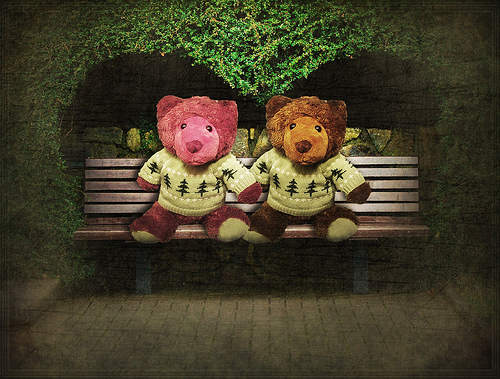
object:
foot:
[215, 218, 250, 244]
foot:
[131, 231, 160, 244]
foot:
[242, 230, 271, 244]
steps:
[1, 277, 64, 328]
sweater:
[138, 147, 257, 217]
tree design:
[147, 161, 238, 197]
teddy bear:
[128, 95, 263, 245]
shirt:
[138, 147, 366, 217]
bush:
[0, 0, 500, 297]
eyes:
[181, 123, 212, 132]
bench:
[73, 156, 428, 296]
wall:
[3, 0, 490, 298]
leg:
[135, 240, 369, 294]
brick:
[6, 293, 490, 373]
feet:
[131, 218, 358, 245]